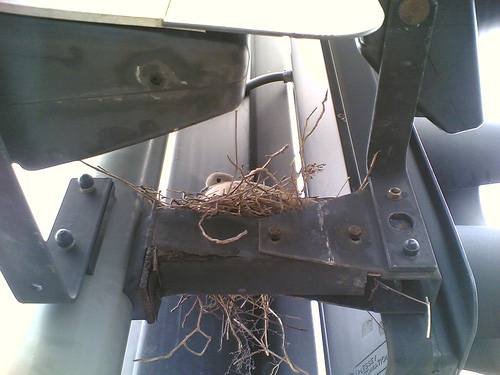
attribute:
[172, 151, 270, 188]
bird — white, small, plump, sitting, little, resting, laying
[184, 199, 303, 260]
nest — brown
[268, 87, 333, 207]
twig — brown, hanging, bare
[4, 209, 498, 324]
structure — iron, silver, metal, black, rusty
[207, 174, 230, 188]
eye — black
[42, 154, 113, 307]
bolts — black, metal, rusty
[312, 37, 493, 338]
bridge — steel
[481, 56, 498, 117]
sky — clear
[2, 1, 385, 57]
projection — curved, white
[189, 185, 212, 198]
beak — grey, tiny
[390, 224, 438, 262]
bolt — rusty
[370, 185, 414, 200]
bolt — gold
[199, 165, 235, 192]
head — little